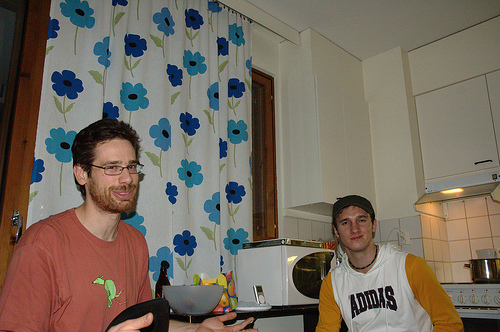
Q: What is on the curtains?
A: Flowers.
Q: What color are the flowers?
A: Blue.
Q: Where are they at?
A: Kitchen.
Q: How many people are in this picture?
A: Two.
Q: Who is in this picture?
A: Two Men.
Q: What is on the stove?
A: Pot.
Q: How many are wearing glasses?
A: One.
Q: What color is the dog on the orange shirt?
A: Green.